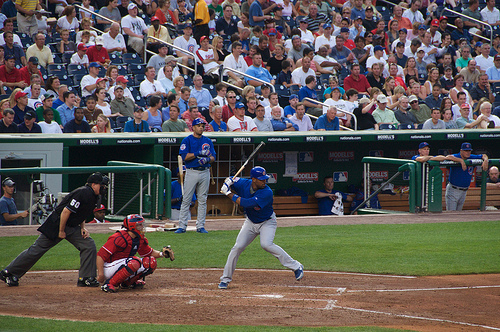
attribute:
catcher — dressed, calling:
[93, 210, 176, 293]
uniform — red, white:
[96, 228, 159, 288]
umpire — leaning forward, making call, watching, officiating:
[2, 170, 113, 290]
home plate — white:
[249, 291, 285, 302]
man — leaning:
[444, 141, 490, 213]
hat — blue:
[459, 139, 475, 155]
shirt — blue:
[448, 152, 486, 191]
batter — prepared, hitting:
[218, 163, 307, 289]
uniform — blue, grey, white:
[218, 175, 304, 281]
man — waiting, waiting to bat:
[171, 116, 221, 235]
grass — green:
[2, 220, 499, 277]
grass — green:
[3, 310, 420, 331]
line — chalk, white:
[345, 278, 499, 299]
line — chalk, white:
[335, 303, 499, 330]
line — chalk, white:
[257, 282, 346, 293]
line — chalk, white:
[1, 308, 100, 324]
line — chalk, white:
[4, 263, 419, 281]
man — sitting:
[312, 175, 357, 216]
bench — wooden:
[250, 178, 499, 222]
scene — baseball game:
[2, 2, 499, 331]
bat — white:
[219, 139, 266, 197]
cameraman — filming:
[2, 178, 38, 226]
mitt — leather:
[160, 244, 175, 264]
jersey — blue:
[168, 176, 200, 209]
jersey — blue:
[227, 175, 276, 224]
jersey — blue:
[349, 187, 381, 215]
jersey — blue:
[317, 187, 350, 217]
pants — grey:
[219, 208, 304, 279]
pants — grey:
[175, 165, 212, 228]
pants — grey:
[445, 183, 469, 211]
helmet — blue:
[249, 163, 270, 185]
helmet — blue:
[191, 115, 208, 128]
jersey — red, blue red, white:
[97, 227, 155, 263]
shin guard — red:
[108, 263, 132, 287]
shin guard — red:
[124, 266, 155, 288]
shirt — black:
[34, 185, 102, 243]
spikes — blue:
[172, 227, 187, 235]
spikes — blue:
[197, 226, 209, 237]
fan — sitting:
[122, 2, 148, 42]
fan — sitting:
[86, 36, 113, 65]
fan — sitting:
[386, 17, 400, 47]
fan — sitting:
[171, 22, 200, 61]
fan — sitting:
[146, 13, 173, 61]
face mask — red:
[135, 213, 146, 238]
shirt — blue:
[9, 103, 36, 124]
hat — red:
[13, 90, 30, 104]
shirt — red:
[221, 103, 238, 126]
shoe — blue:
[216, 280, 230, 290]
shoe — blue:
[293, 266, 305, 282]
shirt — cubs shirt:
[176, 134, 219, 172]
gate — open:
[107, 156, 175, 221]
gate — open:
[360, 153, 421, 216]